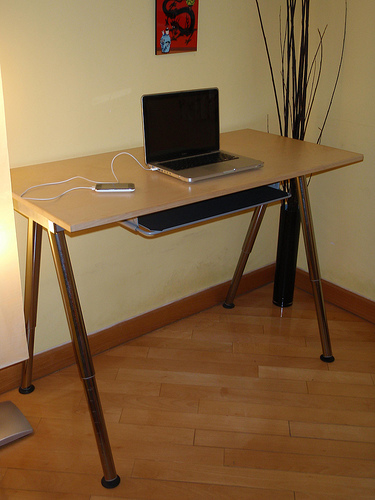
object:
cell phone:
[96, 183, 135, 193]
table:
[8, 126, 364, 487]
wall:
[0, 0, 374, 398]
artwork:
[155, 1, 198, 55]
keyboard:
[159, 150, 239, 171]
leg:
[221, 180, 267, 310]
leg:
[296, 176, 334, 364]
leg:
[19, 215, 42, 396]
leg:
[43, 224, 121, 488]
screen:
[142, 88, 220, 162]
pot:
[271, 186, 301, 309]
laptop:
[141, 87, 263, 182]